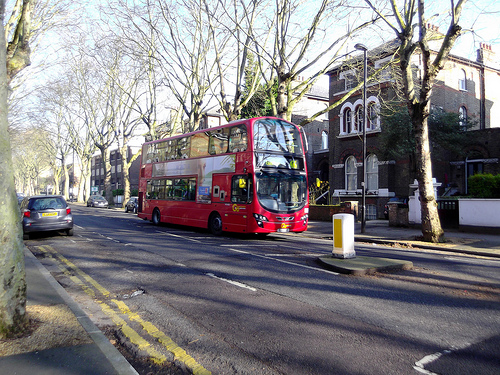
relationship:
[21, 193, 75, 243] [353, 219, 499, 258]
car on side of sidewalk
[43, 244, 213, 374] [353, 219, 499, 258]
line on top of sidewalk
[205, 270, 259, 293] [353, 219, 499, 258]
line on top of sidewalk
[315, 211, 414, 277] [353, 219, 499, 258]
median in middle of sidewalk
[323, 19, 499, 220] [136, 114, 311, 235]
building next to bus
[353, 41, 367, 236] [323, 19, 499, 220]
light post in front of building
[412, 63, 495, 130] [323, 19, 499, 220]
shadow on side of building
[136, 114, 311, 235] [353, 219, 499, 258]
bus on top of sidewalk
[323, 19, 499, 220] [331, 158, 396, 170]
building has trim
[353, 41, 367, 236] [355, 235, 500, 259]
light post on top of curb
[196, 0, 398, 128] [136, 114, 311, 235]
tree behind bus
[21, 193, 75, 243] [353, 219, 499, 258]
car parked on sidewalk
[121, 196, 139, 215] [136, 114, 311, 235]
car behind bus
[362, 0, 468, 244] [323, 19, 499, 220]
tree in front of building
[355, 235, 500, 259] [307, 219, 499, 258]
curb on edge of sidewalk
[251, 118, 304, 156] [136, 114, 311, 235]
window on front of bus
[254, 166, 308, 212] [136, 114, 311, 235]
window on front of bus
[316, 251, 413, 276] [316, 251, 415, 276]
platform on top of platform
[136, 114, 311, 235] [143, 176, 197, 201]
bus has window